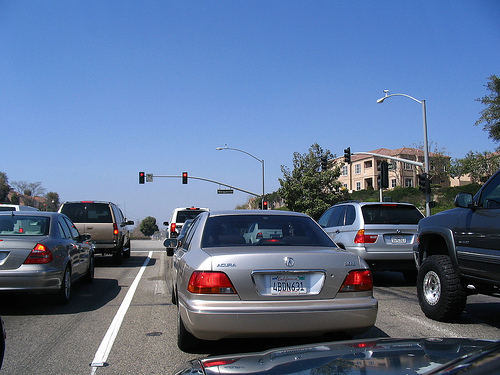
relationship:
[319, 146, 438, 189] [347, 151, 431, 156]
building with roof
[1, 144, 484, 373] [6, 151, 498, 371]
traffic has lanes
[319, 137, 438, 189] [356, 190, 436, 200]
building on hill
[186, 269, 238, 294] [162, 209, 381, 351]
light on car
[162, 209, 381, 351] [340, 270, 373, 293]
car has tail light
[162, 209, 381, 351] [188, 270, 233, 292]
car has tail light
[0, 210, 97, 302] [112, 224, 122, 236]
car has tail light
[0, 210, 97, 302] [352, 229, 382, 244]
car has tail light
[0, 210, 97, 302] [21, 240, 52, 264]
car has light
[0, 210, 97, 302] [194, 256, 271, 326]
car has light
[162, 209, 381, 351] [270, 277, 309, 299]
car has license plate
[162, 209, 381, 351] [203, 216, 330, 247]
car has window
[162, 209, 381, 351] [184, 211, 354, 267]
car has window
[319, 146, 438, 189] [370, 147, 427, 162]
building has roof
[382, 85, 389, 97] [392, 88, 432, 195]
camera on pole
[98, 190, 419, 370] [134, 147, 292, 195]
cars stopped at light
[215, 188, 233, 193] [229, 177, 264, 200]
sign hanging from a pole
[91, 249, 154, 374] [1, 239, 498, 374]
white line painted on a road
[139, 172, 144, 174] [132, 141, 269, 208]
red light on a pole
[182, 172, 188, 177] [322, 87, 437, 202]
light on a pole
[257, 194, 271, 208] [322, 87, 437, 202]
traffic light on a pole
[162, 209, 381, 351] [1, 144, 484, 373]
car waiting in traffic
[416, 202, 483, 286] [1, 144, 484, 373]
car waiting in traffic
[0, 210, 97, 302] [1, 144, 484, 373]
car waiting in traffic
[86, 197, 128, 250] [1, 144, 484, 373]
car waiting in traffic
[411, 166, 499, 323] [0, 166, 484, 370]
car waiting in traffic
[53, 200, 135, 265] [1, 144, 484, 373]
car waiting in traffic